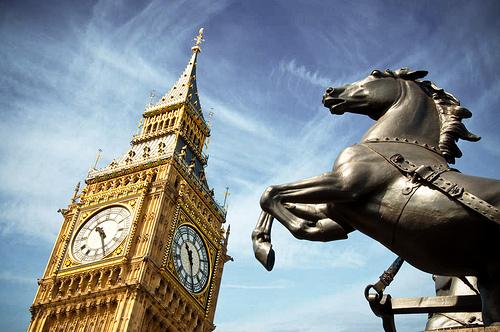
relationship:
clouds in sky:
[88, 58, 112, 69] [271, 30, 277, 33]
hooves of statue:
[253, 253, 303, 275] [317, 58, 451, 260]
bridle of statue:
[347, 113, 443, 153] [317, 58, 451, 260]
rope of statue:
[373, 275, 413, 294] [317, 58, 451, 260]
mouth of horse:
[328, 103, 349, 110] [257, 44, 486, 300]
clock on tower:
[55, 208, 118, 262] [59, 24, 205, 322]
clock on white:
[55, 208, 118, 262] [101, 206, 131, 221]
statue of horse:
[317, 58, 451, 260] [257, 44, 486, 300]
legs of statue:
[228, 171, 332, 264] [317, 58, 451, 260]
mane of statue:
[433, 104, 464, 149] [317, 58, 451, 260]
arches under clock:
[60, 278, 117, 321] [55, 208, 118, 262]